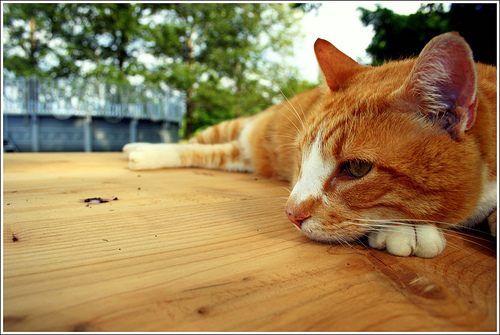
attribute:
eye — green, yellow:
[336, 155, 380, 178]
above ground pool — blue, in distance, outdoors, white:
[4, 77, 183, 153]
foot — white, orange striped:
[367, 220, 447, 259]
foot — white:
[124, 141, 195, 172]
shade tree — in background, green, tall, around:
[7, 6, 131, 92]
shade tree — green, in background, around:
[137, 5, 318, 141]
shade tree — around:
[353, 1, 499, 71]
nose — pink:
[286, 210, 311, 227]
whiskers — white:
[332, 214, 498, 291]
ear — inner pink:
[315, 34, 361, 88]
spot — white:
[294, 135, 338, 199]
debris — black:
[83, 195, 112, 205]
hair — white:
[410, 38, 450, 122]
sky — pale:
[6, 3, 475, 119]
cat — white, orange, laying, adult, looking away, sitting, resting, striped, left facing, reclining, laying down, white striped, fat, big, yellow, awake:
[122, 28, 495, 266]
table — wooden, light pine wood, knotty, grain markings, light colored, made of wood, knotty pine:
[14, 149, 498, 333]